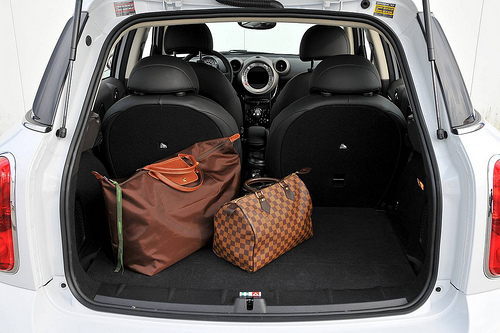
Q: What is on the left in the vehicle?
A: Brown bag.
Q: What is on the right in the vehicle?
A: Yellow and brown bag.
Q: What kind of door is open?
A: Hatchback door.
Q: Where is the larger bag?
A: On the left.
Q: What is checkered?
A: Bag on right.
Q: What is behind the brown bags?
A: Rear driver's side seat.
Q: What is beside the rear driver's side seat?
A: Rear passenger's side seat.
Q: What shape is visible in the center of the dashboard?
A: Circle.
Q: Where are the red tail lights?
A: Right and left of open hatch.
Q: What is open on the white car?
A: Trunk door.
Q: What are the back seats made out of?
A: Leather.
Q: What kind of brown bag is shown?
A: Plain.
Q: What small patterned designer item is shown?
A: Bag.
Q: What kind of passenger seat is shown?
A: Right back.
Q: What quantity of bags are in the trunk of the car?
A: Two bags.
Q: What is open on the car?
A: Trunk.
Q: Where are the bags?
A: In the trunk.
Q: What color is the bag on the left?
A: Brown.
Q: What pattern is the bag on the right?
A: Checkered.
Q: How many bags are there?
A: Two.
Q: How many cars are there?
A: One.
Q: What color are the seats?
A: Black.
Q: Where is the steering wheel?
A: In front of driver seat.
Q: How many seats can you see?
A: Four.